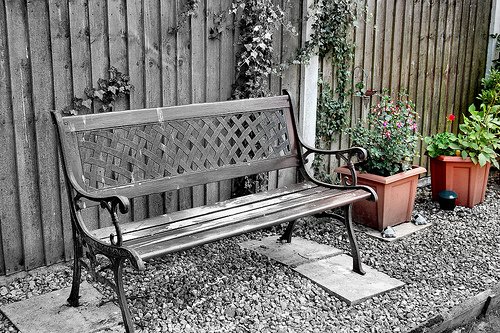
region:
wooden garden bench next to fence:
[34, 90, 386, 320]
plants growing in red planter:
[343, 106, 432, 236]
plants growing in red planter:
[430, 106, 498, 215]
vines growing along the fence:
[226, 7, 280, 103]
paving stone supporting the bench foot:
[302, 248, 401, 305]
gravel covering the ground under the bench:
[138, 270, 307, 330]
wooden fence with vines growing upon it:
[5, 7, 303, 250]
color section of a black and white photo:
[346, 91, 498, 234]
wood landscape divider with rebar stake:
[402, 276, 498, 324]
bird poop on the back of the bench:
[150, 101, 174, 134]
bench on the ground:
[28, 97, 375, 319]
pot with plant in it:
[338, 90, 428, 225]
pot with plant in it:
[427, 88, 494, 209]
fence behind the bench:
[1, 3, 476, 201]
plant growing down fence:
[212, 21, 352, 142]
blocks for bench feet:
[259, 230, 377, 308]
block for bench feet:
[18, 280, 138, 327]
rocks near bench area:
[163, 265, 430, 317]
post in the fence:
[291, 3, 338, 201]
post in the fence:
[471, 5, 498, 160]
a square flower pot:
[311, 120, 426, 255]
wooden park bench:
[39, 75, 423, 312]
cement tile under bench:
[239, 197, 410, 332]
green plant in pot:
[344, 77, 434, 182]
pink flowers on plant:
[355, 90, 431, 177]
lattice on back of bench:
[49, 84, 324, 204]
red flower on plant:
[415, 79, 492, 215]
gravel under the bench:
[184, 247, 343, 331]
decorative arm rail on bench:
[263, 84, 384, 262]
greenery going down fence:
[301, 5, 379, 210]